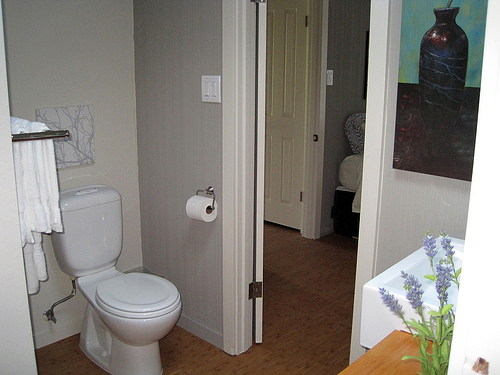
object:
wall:
[302, 4, 363, 238]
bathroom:
[302, 4, 393, 202]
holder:
[172, 179, 228, 229]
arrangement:
[356, 232, 466, 349]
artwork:
[414, 12, 471, 150]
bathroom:
[0, 0, 489, 371]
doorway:
[216, 0, 438, 361]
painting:
[391, 0, 476, 182]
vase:
[379, 1, 487, 180]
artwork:
[28, 103, 109, 172]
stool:
[39, 182, 187, 369]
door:
[242, 0, 371, 374]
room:
[256, 13, 371, 329]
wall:
[357, 0, 473, 234]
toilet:
[52, 183, 209, 334]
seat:
[77, 265, 199, 319]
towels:
[8, 116, 90, 296]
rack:
[8, 117, 71, 150]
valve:
[28, 254, 92, 345]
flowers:
[400, 270, 425, 318]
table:
[337, 326, 445, 375]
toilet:
[25, 119, 225, 370]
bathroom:
[0, 122, 212, 366]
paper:
[185, 197, 217, 227]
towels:
[11, 114, 96, 294]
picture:
[391, 0, 477, 182]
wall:
[365, 3, 439, 354]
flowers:
[371, 285, 409, 327]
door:
[266, 1, 305, 232]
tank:
[49, 173, 125, 276]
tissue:
[183, 194, 217, 222]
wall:
[133, 2, 223, 352]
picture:
[34, 105, 95, 168]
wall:
[0, 1, 144, 354]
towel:
[12, 116, 62, 305]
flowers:
[423, 229, 457, 304]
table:
[332, 325, 445, 375]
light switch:
[199, 75, 224, 105]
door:
[250, 4, 267, 348]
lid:
[79, 261, 185, 317]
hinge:
[248, 281, 262, 300]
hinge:
[249, 1, 266, 4]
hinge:
[297, 191, 303, 204]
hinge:
[303, 14, 310, 28]